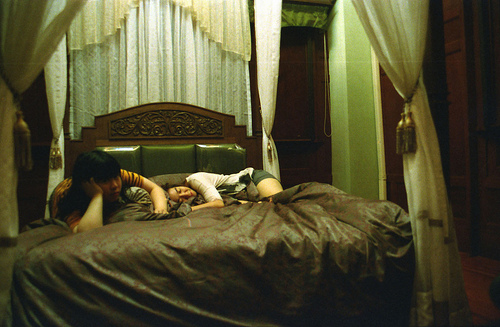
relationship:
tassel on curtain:
[394, 108, 418, 157] [344, 0, 478, 326]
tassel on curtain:
[11, 106, 35, 174] [0, 0, 95, 325]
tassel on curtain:
[46, 135, 64, 171] [41, 32, 71, 222]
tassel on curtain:
[264, 138, 277, 165] [248, 0, 289, 190]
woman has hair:
[151, 164, 286, 201] [160, 180, 187, 190]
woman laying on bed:
[151, 164, 286, 201] [6, 99, 427, 327]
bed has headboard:
[6, 99, 427, 327] [55, 102, 268, 187]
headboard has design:
[55, 102, 268, 187] [105, 109, 228, 142]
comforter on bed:
[9, 172, 415, 326] [6, 99, 427, 327]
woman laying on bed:
[48, 147, 174, 235] [6, 99, 427, 327]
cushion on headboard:
[194, 140, 246, 176] [55, 102, 268, 187]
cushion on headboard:
[141, 142, 199, 177] [55, 102, 268, 187]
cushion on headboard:
[93, 144, 142, 175] [55, 102, 268, 187]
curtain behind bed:
[64, 0, 254, 142] [6, 99, 427, 327]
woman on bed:
[151, 164, 286, 201] [6, 99, 427, 327]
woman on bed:
[48, 147, 174, 235] [6, 99, 427, 327]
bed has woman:
[6, 99, 427, 327] [151, 164, 286, 201]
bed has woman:
[6, 99, 427, 327] [48, 147, 174, 235]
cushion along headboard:
[194, 140, 246, 176] [55, 102, 268, 187]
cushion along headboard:
[141, 142, 199, 177] [55, 102, 268, 187]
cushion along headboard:
[93, 144, 142, 175] [55, 102, 268, 187]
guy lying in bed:
[151, 164, 286, 201] [6, 99, 427, 327]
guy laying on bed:
[48, 147, 174, 235] [6, 99, 427, 327]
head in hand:
[69, 151, 123, 200] [81, 176, 108, 201]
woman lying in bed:
[151, 164, 286, 201] [6, 99, 427, 327]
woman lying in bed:
[48, 147, 174, 235] [6, 99, 427, 327]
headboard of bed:
[55, 102, 268, 187] [6, 99, 427, 327]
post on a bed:
[244, 0, 264, 137] [6, 99, 427, 327]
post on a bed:
[60, 22, 76, 144] [6, 99, 427, 327]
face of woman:
[167, 187, 199, 202] [151, 164, 286, 201]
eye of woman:
[175, 186, 182, 195] [151, 164, 286, 201]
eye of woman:
[179, 198, 184, 204] [151, 164, 286, 201]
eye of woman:
[113, 174, 119, 180] [48, 147, 174, 235]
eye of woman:
[103, 177, 110, 187] [48, 147, 174, 235]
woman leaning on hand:
[48, 147, 174, 235] [81, 176, 108, 201]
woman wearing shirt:
[151, 164, 286, 201] [180, 162, 256, 205]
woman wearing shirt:
[48, 147, 174, 235] [48, 169, 147, 231]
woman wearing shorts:
[151, 164, 286, 201] [246, 168, 278, 187]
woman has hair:
[48, 147, 174, 235] [55, 147, 124, 216]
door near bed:
[241, 21, 340, 195] [6, 99, 427, 327]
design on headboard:
[105, 109, 228, 142] [55, 102, 268, 187]